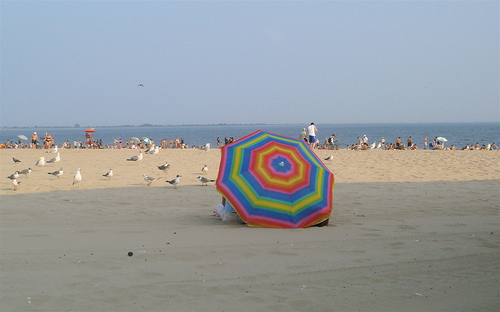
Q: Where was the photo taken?
A: At beach.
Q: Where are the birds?
A: On sand.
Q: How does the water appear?
A: Calm.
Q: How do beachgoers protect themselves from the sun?
A: Umbrella.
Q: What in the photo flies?
A: Birds.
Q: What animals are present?
A: Birds.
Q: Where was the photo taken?
A: Beach.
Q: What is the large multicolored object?
A: Umbrella.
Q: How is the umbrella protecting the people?
A: Shading them.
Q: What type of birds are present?
A: Seagulls.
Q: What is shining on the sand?
A: Sun.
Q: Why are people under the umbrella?
A: Shade.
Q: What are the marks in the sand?
A: Footprints.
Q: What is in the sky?
A: Bird.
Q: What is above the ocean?
A: The grey sky.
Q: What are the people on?
A: The sandy beach.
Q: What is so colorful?
A: The umbrella.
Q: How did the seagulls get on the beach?
A: They flew.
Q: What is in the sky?
A: A seagull.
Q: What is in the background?
A: The water is in the background.